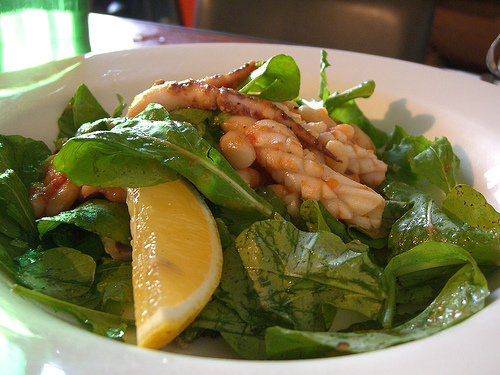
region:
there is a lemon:
[137, 176, 219, 346]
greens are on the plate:
[223, 238, 472, 347]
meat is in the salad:
[222, 114, 383, 227]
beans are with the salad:
[216, 126, 249, 173]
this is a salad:
[85, 95, 476, 357]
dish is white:
[18, 88, 70, 140]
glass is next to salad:
[0, 3, 93, 55]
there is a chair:
[210, 1, 437, 65]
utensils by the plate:
[129, 18, 181, 49]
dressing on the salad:
[220, 118, 388, 225]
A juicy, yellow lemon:
[120, 175, 226, 347]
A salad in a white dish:
[2, 42, 497, 372]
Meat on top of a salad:
[122, 55, 387, 234]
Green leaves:
[230, 210, 495, 362]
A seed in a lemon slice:
[152, 253, 182, 275]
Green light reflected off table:
[0, 0, 82, 77]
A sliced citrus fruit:
[113, 167, 225, 352]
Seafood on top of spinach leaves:
[216, 90, 391, 240]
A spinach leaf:
[59, 115, 278, 222]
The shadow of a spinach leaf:
[370, 97, 440, 143]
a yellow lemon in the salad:
[125, 168, 230, 353]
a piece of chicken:
[125, 56, 355, 170]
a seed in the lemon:
[151, 257, 181, 277]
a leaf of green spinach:
[51, 111, 277, 227]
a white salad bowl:
[0, 39, 497, 374]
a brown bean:
[219, 129, 256, 173]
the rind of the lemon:
[171, 174, 228, 286]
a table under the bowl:
[0, 0, 323, 80]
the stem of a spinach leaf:
[325, 76, 390, 112]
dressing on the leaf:
[410, 183, 498, 260]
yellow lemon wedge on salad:
[116, 158, 221, 348]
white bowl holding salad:
[399, 67, 499, 162]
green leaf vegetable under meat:
[228, 213, 371, 350]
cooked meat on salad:
[222, 104, 372, 209]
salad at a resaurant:
[5, 49, 492, 358]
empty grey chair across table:
[159, 1, 434, 70]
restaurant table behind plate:
[91, 15, 258, 53]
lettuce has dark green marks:
[247, 218, 372, 326]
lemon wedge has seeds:
[137, 225, 205, 313]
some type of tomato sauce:
[22, 142, 92, 226]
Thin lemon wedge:
[108, 149, 238, 361]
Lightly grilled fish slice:
[124, 56, 395, 240]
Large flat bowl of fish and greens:
[1, 44, 498, 371]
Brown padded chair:
[183, 0, 446, 77]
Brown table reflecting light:
[1, 1, 496, 184]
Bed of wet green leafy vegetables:
[52, 117, 494, 354]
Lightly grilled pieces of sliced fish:
[119, 57, 403, 239]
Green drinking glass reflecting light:
[33, 0, 103, 62]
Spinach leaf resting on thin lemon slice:
[42, 101, 291, 223]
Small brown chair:
[420, 0, 497, 97]